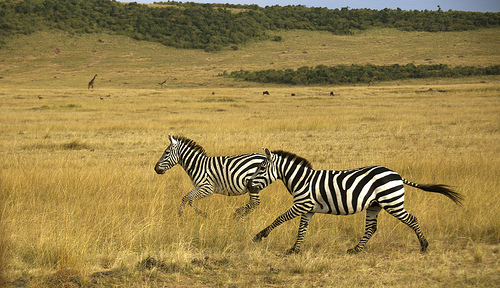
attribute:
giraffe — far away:
[86, 70, 98, 92]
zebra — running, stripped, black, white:
[247, 148, 464, 262]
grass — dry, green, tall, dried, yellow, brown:
[0, 86, 495, 286]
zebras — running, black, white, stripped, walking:
[155, 135, 462, 255]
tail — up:
[403, 176, 463, 207]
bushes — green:
[1, 3, 500, 57]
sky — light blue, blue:
[209, 1, 498, 26]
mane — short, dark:
[270, 148, 313, 168]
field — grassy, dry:
[7, 32, 498, 283]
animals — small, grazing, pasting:
[263, 90, 338, 106]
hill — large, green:
[1, 1, 500, 47]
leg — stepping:
[247, 202, 308, 244]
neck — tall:
[93, 78, 97, 81]